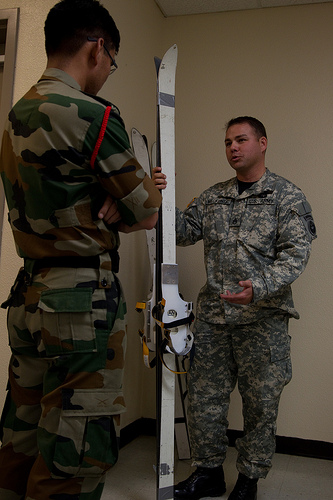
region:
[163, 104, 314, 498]
man wearing a US Army uniform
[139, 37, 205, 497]
a pair of white skis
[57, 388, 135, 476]
pocket on the side of the pants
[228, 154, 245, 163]
mouth is slightly open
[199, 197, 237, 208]
name tape on the uniform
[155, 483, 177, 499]
silver stripe on the bottom of the ski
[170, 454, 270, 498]
a pair of black boots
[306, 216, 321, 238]
emblem on the sleeve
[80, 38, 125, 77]
glasses on the face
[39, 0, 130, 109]
head is tilted down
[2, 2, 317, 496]
two men in military uniforms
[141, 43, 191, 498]
vertical skis in hand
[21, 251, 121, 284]
black belt in loop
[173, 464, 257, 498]
black boots on soldier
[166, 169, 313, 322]
open collar of camouflage shirt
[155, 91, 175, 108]
duct tape around two skis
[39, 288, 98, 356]
back pocket of pants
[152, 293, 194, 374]
boot straps on ski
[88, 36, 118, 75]
eyeglass arm over ear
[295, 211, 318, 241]
emblem on shirt sleeve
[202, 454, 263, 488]
Two men standing up talking.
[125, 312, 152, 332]
Two men standing up talking.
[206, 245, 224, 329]
Two men standing up talking.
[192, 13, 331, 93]
a biege painted wall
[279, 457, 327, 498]
part of a white tile floor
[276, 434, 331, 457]
part of a black floor base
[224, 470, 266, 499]
part of a man's black boot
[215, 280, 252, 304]
the hand of a man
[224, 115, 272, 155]
a man's short cut black hair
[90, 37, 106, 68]
the ear of a man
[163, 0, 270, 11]
part of a white ceiling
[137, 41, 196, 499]
a pair of long skis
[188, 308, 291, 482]
a pair of military pants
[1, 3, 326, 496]
two people with military uniforms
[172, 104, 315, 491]
man wearing camouflage suit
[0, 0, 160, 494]
man wearing camouflage suit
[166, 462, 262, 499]
a pair of black boots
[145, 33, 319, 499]
man holding a pair of skis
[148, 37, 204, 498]
a pair of gray skis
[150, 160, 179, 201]
a hand holding skis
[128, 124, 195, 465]
skis leans on wall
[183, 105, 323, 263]
the man is talking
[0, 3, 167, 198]
person wears a pair of glasses